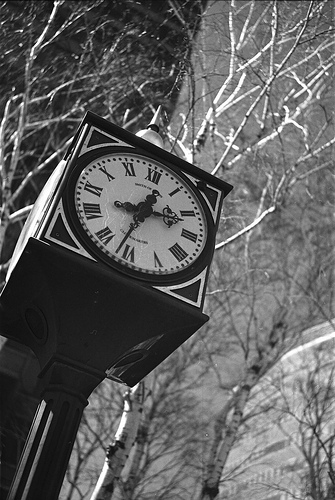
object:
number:
[152, 247, 163, 267]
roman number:
[120, 243, 138, 265]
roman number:
[94, 224, 113, 248]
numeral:
[180, 225, 200, 243]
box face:
[39, 123, 224, 314]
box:
[0, 112, 234, 390]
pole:
[5, 394, 85, 498]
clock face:
[74, 152, 208, 276]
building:
[204, 321, 335, 499]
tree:
[0, 0, 335, 274]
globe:
[135, 123, 165, 151]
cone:
[147, 103, 165, 130]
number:
[166, 182, 183, 197]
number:
[84, 201, 102, 221]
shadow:
[42, 383, 84, 431]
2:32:
[114, 187, 185, 255]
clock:
[63, 144, 216, 287]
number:
[167, 241, 189, 264]